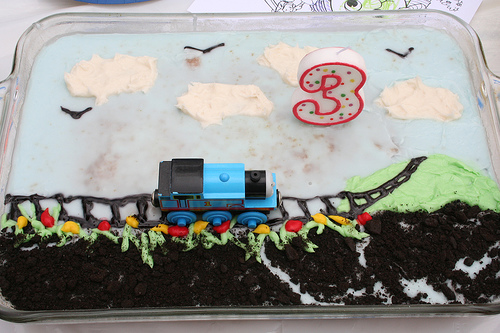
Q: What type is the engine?
A: Little toy train.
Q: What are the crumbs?
A: Chocolate Oreo Cookie.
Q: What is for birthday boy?
A: Birthday cake.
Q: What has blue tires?
A: Blue Toy Engine.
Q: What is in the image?
A: Birthday cake.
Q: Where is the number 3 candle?
A: Top of cake.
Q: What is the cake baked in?
A: Glass cake pan.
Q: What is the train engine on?
A: Black tracks.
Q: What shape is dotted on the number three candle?
A: Circles.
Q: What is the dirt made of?
A: Crumbled chocolate cake.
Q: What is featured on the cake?
A: Toy train.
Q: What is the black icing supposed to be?
A: Train tracks.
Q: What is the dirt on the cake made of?
A: Crushed oreos.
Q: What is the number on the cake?
A: 3.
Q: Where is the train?
A: On the cake.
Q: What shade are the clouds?
A: White.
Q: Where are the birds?
A: On the cake.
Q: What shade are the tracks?
A: Black.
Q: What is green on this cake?
A: The mountain.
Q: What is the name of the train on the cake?
A: Thomas The Tank Engine.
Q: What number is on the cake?
A: 3.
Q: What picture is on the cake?
A: Train on tracks.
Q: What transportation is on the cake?
A: A train.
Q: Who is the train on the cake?
A: Thomas the Train.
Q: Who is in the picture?
A: Nobody is in the picture.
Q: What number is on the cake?
A: The number 3.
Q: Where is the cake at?
A: On the table.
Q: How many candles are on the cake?
A: 1 candle.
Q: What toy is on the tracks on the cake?
A: A blue train.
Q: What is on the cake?
A: A train and a candle.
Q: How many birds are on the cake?
A: 3 birds.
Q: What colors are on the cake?
A: Blue, white, green and black.